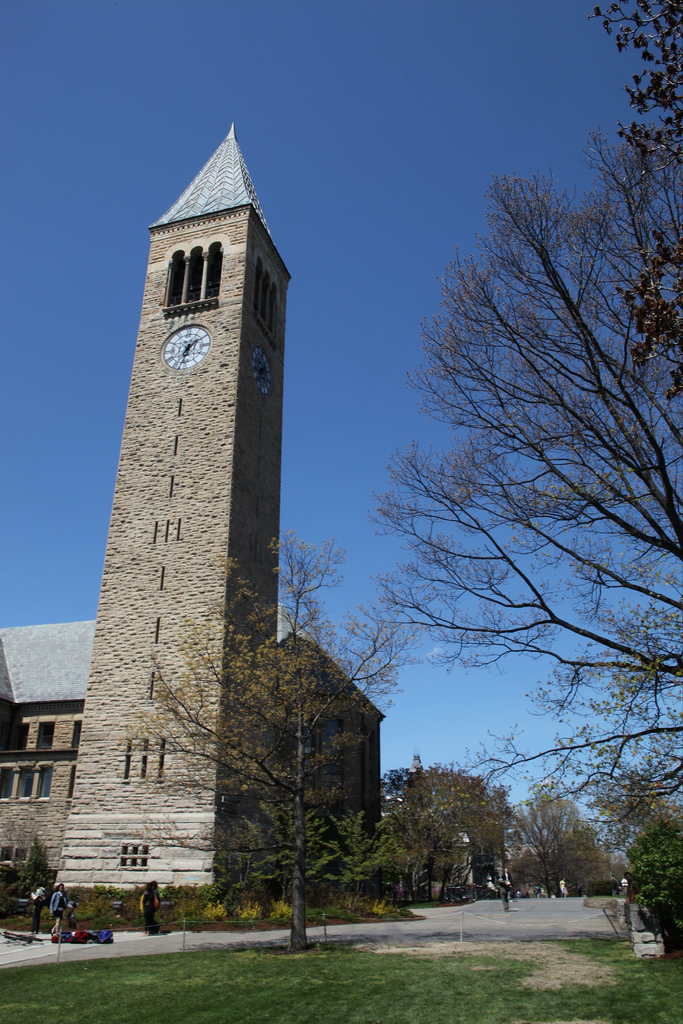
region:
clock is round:
[156, 324, 211, 372]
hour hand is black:
[185, 334, 204, 349]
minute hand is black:
[176, 344, 189, 362]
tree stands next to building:
[119, 520, 418, 957]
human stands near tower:
[27, 884, 48, 934]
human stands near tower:
[46, 881, 68, 939]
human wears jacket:
[138, 876, 161, 929]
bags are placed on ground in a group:
[48, 927, 117, 946]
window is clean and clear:
[184, 252, 203, 302]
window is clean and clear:
[202, 251, 225, 302]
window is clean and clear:
[36, 766, 54, 802]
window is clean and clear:
[1, 766, 15, 798]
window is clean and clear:
[38, 719, 57, 753]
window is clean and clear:
[72, 722, 79, 756]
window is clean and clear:
[123, 737, 130, 783]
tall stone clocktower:
[64, 114, 293, 912]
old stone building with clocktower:
[0, 108, 392, 897]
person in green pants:
[483, 860, 531, 912]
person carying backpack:
[128, 870, 168, 932]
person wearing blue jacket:
[46, 879, 77, 931]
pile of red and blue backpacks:
[41, 926, 121, 948]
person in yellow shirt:
[555, 872, 572, 897]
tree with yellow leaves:
[123, 526, 423, 962]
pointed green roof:
[122, 116, 308, 281]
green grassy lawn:
[5, 923, 681, 1022]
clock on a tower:
[147, 320, 219, 373]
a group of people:
[14, 862, 187, 944]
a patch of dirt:
[383, 904, 619, 1003]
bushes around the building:
[28, 865, 375, 933]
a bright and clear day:
[4, 7, 675, 1022]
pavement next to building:
[13, 889, 621, 968]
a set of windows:
[156, 231, 225, 318]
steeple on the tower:
[143, 95, 272, 230]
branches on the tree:
[273, 148, 681, 880]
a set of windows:
[5, 710, 63, 807]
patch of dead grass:
[365, 919, 630, 1011]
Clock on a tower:
[153, 324, 219, 380]